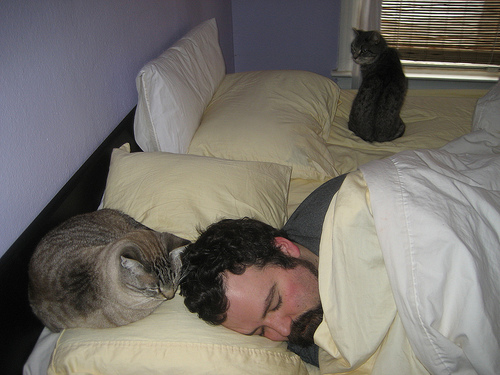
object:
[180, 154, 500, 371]
man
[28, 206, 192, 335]
cat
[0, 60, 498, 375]
bed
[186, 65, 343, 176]
pillow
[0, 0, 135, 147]
wall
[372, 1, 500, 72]
window